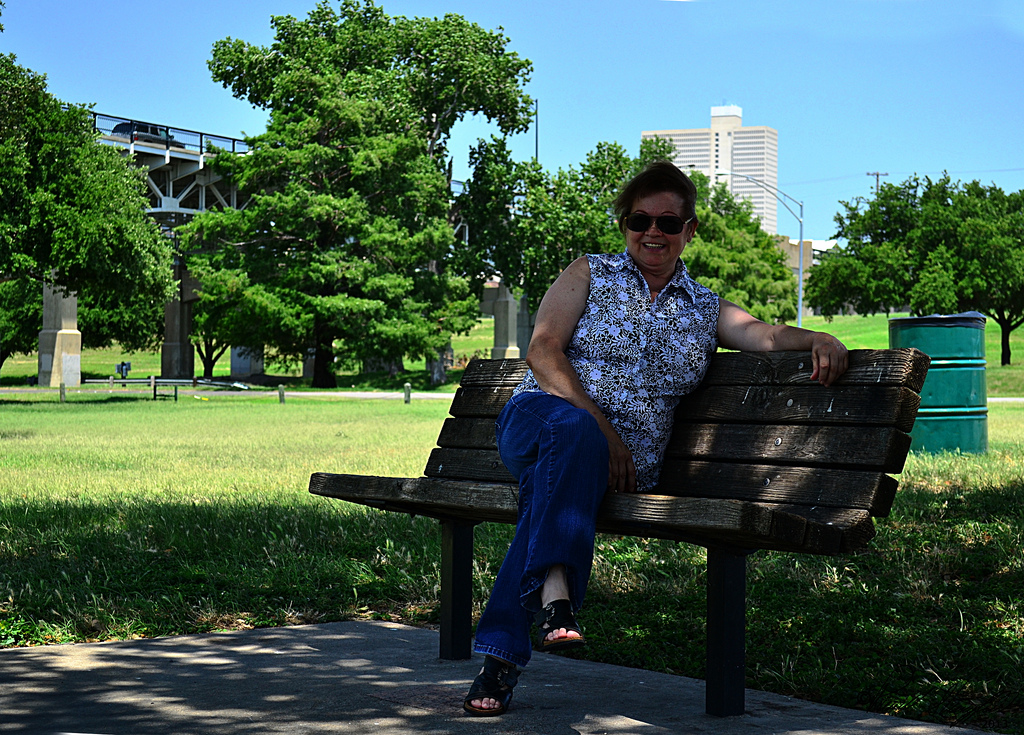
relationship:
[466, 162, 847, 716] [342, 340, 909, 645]
woman sitting on bench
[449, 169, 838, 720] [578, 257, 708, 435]
woman wears floral shirt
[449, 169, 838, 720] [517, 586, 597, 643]
woman wears sandal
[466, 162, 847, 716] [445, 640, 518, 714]
woman wears sandal